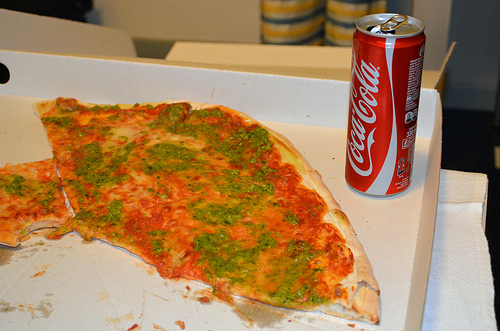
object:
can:
[343, 9, 420, 199]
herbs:
[145, 185, 157, 193]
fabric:
[260, 1, 386, 45]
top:
[380, 10, 409, 35]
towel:
[419, 160, 495, 330]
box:
[1, 47, 446, 330]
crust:
[220, 105, 383, 323]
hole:
[0, 61, 12, 85]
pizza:
[1, 97, 381, 327]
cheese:
[2, 98, 355, 306]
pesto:
[0, 96, 356, 312]